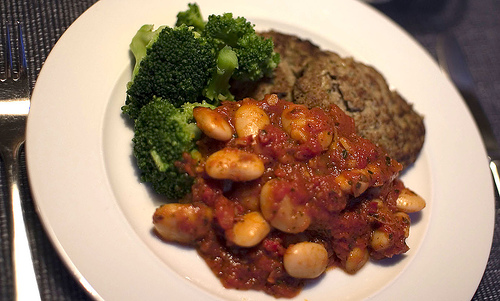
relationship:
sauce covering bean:
[276, 116, 385, 173] [259, 178, 312, 232]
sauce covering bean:
[276, 116, 385, 173] [330, 161, 374, 193]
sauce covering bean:
[276, 116, 385, 173] [279, 96, 334, 151]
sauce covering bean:
[276, 116, 385, 173] [232, 99, 273, 149]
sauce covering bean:
[276, 116, 385, 173] [360, 153, 400, 183]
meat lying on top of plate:
[278, 54, 457, 163] [22, 1, 482, 299]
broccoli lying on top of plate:
[123, 6, 273, 196] [22, 1, 482, 299]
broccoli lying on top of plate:
[201, 47, 240, 105] [22, 1, 482, 299]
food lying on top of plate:
[123, 2, 427, 291] [22, 1, 482, 299]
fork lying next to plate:
[0, 18, 42, 300] [22, 1, 482, 299]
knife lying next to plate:
[441, 26, 493, 116] [22, 1, 482, 299]